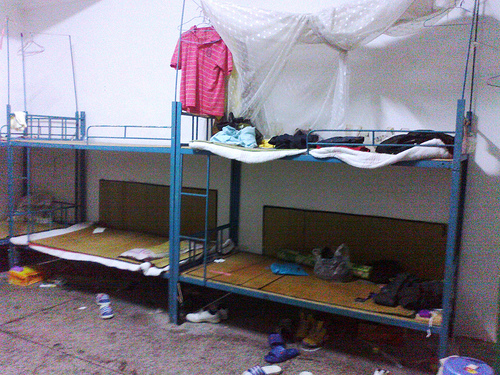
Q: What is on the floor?
A: Shoes.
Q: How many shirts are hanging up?
A: One.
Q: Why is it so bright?
A: Light is on.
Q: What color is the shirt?
A: Pink.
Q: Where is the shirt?
A: Hanging up.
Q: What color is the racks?
A: Blue.